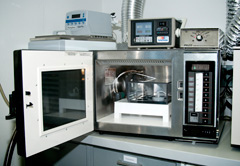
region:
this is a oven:
[17, 46, 215, 157]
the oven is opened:
[95, 57, 181, 127]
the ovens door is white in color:
[22, 57, 90, 142]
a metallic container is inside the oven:
[127, 80, 170, 98]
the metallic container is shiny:
[128, 80, 168, 101]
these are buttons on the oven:
[203, 74, 210, 122]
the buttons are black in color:
[202, 74, 210, 122]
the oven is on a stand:
[82, 142, 160, 163]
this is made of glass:
[46, 71, 82, 123]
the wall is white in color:
[156, 2, 222, 15]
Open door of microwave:
[16, 52, 106, 131]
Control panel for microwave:
[186, 51, 218, 130]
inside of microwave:
[91, 58, 175, 125]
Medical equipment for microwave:
[60, 9, 119, 47]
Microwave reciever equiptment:
[178, 27, 226, 52]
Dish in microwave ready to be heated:
[124, 79, 172, 113]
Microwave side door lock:
[3, 86, 39, 135]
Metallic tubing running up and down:
[217, 1, 237, 25]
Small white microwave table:
[109, 97, 172, 127]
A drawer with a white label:
[80, 150, 143, 163]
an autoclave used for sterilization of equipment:
[12, 49, 225, 158]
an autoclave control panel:
[184, 60, 214, 125]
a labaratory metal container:
[124, 72, 154, 101]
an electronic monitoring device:
[127, 17, 177, 47]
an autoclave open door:
[13, 48, 95, 158]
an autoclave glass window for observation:
[40, 68, 85, 131]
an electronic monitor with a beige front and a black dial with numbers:
[179, 27, 219, 48]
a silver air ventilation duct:
[121, 0, 145, 42]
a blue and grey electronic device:
[65, 10, 113, 38]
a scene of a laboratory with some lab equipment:
[0, 0, 239, 165]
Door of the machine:
[12, 50, 95, 156]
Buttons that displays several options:
[183, 54, 214, 138]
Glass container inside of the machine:
[127, 80, 171, 102]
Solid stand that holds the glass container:
[114, 100, 169, 119]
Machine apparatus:
[14, 49, 212, 153]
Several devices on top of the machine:
[127, 19, 221, 46]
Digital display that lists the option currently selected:
[192, 62, 209, 69]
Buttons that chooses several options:
[202, 70, 206, 121]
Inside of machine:
[93, 61, 170, 123]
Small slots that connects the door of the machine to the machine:
[176, 79, 183, 99]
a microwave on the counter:
[91, 51, 218, 140]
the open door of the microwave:
[14, 50, 98, 148]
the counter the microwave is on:
[73, 132, 237, 164]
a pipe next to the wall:
[122, 0, 145, 40]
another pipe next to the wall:
[224, 0, 239, 49]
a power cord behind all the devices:
[222, 65, 232, 124]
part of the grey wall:
[1, 1, 67, 51]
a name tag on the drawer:
[120, 153, 139, 163]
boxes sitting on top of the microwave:
[124, 18, 220, 52]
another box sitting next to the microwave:
[60, 11, 115, 37]